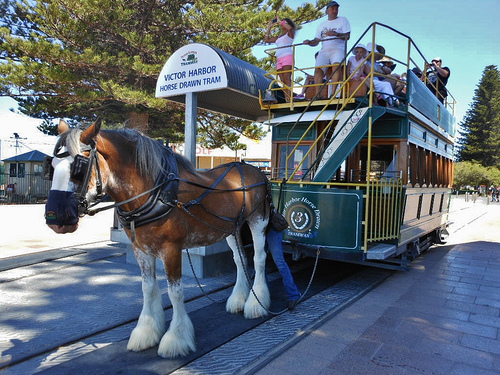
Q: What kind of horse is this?
A: Clydesdale.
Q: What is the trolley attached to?
A: Horse.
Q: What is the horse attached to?
A: Trolley.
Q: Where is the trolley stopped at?
A: Waiting station.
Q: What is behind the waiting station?
A: Tree.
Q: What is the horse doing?
A: Pulling the trolley.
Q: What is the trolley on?
A: Tracks.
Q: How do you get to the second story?
A: Stairs.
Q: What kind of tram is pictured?
A: Horse drawn.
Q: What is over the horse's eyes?
A: Blinders.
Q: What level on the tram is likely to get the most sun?
A: Top.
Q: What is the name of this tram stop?
A: Victor Harbor.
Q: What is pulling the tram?
A: A horse.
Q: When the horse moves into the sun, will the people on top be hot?
A: Yes.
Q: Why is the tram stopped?
A: For people to get on.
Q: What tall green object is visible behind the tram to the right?
A: A tree.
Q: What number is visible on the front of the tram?
A: 3.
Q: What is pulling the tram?
A: The horse.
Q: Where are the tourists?
A: On the tram.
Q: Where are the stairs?
A: On the tram.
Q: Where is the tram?
A: On the street.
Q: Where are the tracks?
A: On the street.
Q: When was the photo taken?
A: Daytime.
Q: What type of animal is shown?
A: Horse.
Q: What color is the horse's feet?
A: White.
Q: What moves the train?
A: Horse.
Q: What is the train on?
A: Track.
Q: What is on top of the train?
A: People.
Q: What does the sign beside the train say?
A: Victor Harbor Horse Drawn Train.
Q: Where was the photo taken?
A: In a historical area that gives tours.